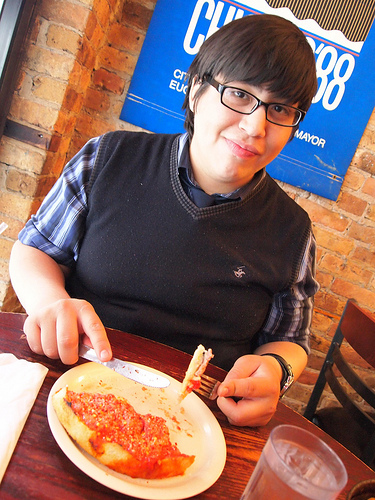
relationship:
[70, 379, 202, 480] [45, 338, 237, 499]
pizza on plate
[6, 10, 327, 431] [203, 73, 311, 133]
man wearing glasses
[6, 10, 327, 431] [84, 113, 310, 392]
man in vest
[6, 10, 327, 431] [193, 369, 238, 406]
man holding fork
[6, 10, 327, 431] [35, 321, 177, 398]
man holding knife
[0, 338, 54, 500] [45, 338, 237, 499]
napkin next to plate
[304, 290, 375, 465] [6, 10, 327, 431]
chair behind man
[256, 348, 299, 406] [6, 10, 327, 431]
watch on man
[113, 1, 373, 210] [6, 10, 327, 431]
poster behind man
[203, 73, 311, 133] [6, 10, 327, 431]
glasses on man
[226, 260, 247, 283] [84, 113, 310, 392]
logo on vest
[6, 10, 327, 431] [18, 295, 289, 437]
man has hands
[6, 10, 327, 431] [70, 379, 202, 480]
man eating pizza